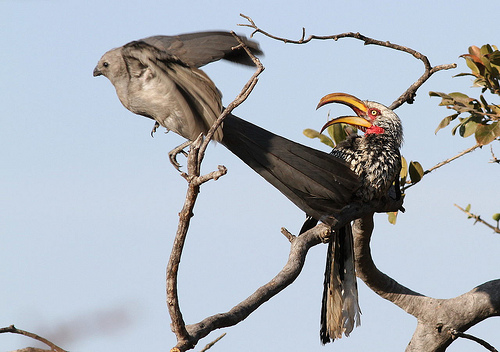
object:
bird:
[314, 91, 413, 346]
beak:
[314, 91, 374, 137]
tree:
[235, 13, 497, 352]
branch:
[237, 6, 455, 108]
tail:
[318, 221, 366, 346]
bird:
[91, 36, 372, 221]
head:
[92, 46, 128, 81]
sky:
[0, 2, 499, 351]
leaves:
[407, 159, 423, 182]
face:
[363, 100, 388, 142]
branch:
[162, 31, 268, 352]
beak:
[91, 64, 104, 80]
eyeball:
[101, 59, 111, 71]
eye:
[369, 108, 380, 118]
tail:
[220, 99, 379, 230]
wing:
[138, 30, 263, 70]